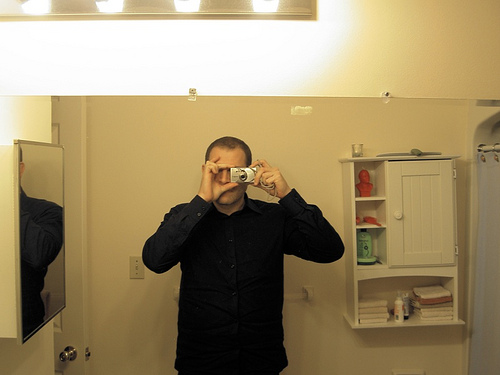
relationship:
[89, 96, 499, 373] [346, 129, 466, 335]
wall mounted cabinet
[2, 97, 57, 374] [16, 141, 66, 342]
wall mounted mirror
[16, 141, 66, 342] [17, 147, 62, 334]
mirror with reflection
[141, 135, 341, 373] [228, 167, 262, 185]
guy holding camera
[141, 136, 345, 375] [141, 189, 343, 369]
guy in shirt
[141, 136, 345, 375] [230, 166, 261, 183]
guy taking selfie with a camera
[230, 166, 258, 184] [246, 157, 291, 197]
camera in a hand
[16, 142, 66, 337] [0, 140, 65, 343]
mirror and cabinet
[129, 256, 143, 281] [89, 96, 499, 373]
lightswitch on wall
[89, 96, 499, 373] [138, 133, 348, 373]
wall behind person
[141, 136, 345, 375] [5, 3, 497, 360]
guy taking selfie in bathroom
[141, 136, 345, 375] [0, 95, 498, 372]
guy using mirror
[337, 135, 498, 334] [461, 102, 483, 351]
washclothes next to shower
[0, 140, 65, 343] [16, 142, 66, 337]
cabinet has mirror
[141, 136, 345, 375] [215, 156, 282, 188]
guy using camera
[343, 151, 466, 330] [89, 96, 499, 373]
shelving on wall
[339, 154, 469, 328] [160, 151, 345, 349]
bathroom shelf behind person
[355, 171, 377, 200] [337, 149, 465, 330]
bust on shelf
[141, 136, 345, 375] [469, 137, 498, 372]
guy next to shower curtain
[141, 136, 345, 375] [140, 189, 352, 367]
guy wearing button down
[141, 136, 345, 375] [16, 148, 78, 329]
guy in mirror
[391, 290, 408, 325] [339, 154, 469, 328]
bottle on bathroom shelf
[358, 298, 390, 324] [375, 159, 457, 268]
towels under door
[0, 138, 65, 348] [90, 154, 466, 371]
cabinet on wall